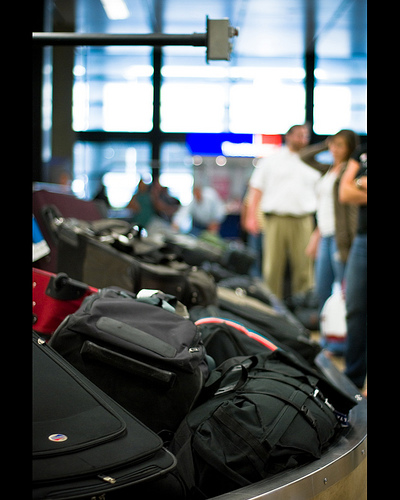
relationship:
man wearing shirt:
[255, 101, 321, 308] [254, 146, 320, 233]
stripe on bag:
[189, 305, 286, 367] [189, 310, 339, 373]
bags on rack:
[33, 204, 280, 498] [180, 435, 366, 496]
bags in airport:
[33, 204, 280, 498] [61, 12, 362, 327]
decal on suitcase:
[46, 424, 71, 451] [32, 354, 168, 492]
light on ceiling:
[88, 0, 143, 22] [72, 0, 352, 56]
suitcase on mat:
[32, 354, 168, 492] [241, 285, 361, 498]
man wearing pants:
[255, 101, 321, 308] [261, 204, 316, 324]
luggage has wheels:
[35, 264, 52, 341] [47, 269, 73, 294]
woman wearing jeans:
[309, 126, 349, 334] [309, 236, 350, 308]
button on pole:
[224, 17, 241, 49] [39, 17, 208, 65]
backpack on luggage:
[189, 310, 339, 373] [35, 264, 52, 341]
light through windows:
[171, 86, 216, 126] [99, 61, 312, 133]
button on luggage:
[47, 435, 67, 443] [41, 380, 124, 469]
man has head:
[255, 101, 321, 308] [283, 124, 316, 156]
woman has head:
[309, 126, 349, 334] [328, 129, 360, 165]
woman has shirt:
[309, 126, 349, 334] [316, 173, 342, 234]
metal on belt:
[313, 385, 332, 421] [235, 376, 320, 404]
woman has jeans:
[309, 126, 349, 334] [309, 236, 350, 308]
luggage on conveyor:
[33, 204, 280, 498] [241, 285, 361, 498]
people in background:
[250, 113, 381, 357] [111, 35, 363, 236]